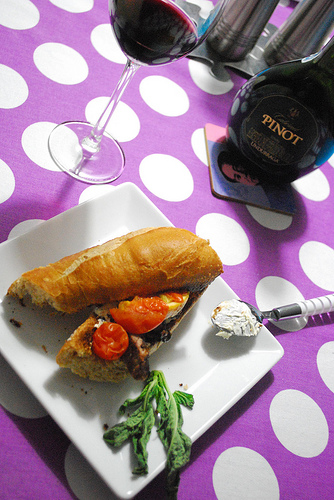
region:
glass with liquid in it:
[45, 1, 211, 188]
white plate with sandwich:
[0, 182, 284, 494]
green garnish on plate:
[102, 369, 195, 483]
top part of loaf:
[4, 221, 222, 296]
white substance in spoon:
[211, 298, 259, 337]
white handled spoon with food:
[207, 291, 333, 335]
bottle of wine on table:
[228, 10, 332, 182]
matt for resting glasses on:
[199, 122, 299, 215]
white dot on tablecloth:
[33, 38, 93, 85]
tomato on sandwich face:
[93, 320, 129, 359]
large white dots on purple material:
[7, 12, 327, 490]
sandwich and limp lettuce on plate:
[3, 182, 282, 485]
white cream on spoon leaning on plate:
[207, 291, 328, 334]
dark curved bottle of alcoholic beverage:
[222, 26, 327, 179]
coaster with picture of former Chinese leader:
[202, 117, 298, 215]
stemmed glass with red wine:
[42, 0, 216, 180]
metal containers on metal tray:
[192, 0, 325, 80]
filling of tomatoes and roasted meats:
[78, 286, 201, 365]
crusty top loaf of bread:
[6, 221, 221, 307]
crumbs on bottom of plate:
[9, 275, 94, 398]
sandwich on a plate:
[6, 223, 223, 383]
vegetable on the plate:
[102, 367, 195, 477]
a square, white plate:
[0, 181, 284, 498]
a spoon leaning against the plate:
[211, 289, 333, 338]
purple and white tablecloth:
[0, 0, 333, 499]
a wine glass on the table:
[47, 0, 228, 183]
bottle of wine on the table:
[226, 27, 332, 185]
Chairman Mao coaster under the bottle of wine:
[204, 121, 297, 217]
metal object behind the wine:
[189, 0, 333, 82]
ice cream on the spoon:
[211, 296, 263, 337]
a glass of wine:
[45, 0, 207, 184]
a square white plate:
[0, 186, 277, 490]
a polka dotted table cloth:
[214, 418, 326, 489]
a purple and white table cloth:
[186, 438, 327, 493]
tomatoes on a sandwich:
[70, 296, 164, 363]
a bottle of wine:
[225, 40, 327, 183]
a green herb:
[98, 371, 208, 486]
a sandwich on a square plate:
[23, 224, 222, 399]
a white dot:
[136, 149, 195, 207]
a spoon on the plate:
[212, 294, 331, 338]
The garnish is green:
[75, 361, 210, 482]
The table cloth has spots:
[211, 393, 316, 494]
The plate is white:
[38, 362, 153, 465]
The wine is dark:
[109, 2, 201, 75]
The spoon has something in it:
[204, 273, 277, 346]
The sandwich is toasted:
[19, 228, 202, 386]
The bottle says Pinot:
[247, 99, 320, 165]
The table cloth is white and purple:
[245, 399, 321, 496]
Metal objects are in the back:
[216, 3, 322, 83]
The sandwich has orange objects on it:
[84, 296, 159, 383]